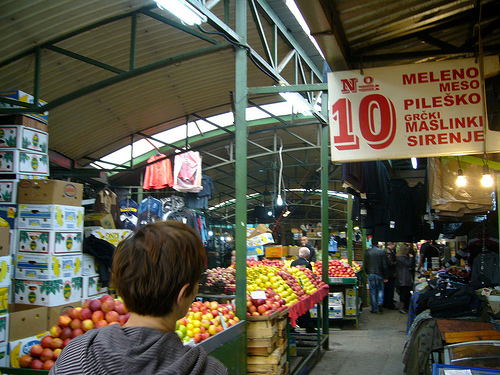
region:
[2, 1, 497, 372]
open fruit market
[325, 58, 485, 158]
red and white sale sign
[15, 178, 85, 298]
white, green, yellow and blue stacked boxes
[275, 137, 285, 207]
light bulb hanging from the ceiling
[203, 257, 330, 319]
a table full of fruit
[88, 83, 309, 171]
skylight in the ceiling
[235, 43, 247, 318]
tall green wood board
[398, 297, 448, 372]
a man shopping at the fruit market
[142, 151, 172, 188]
red jacket hanging from the ceiling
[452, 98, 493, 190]
two lamps hanging from the ceiling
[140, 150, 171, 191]
a red coat hanging from the ceiling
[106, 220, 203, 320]
the head of a person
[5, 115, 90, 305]
a stack of a boxes of a bananas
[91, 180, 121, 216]
a brown coat hanging from the ceiling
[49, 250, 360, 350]
bins of a many fruits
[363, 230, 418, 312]
people in the isle of a market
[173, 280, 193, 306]
the ear of a person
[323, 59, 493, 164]
a white sign with read letters and numbers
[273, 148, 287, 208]
a light hanging from the ceiling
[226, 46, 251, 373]
a metal pole of a building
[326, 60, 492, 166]
white sign is hanging from the ceiling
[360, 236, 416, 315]
a couple is walking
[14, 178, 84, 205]
brown cardboard box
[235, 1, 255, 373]
tall green metal pole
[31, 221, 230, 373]
person is standing next to a table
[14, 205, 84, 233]
white box on top of white box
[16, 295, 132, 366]
fruit stacked on table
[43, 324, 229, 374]
person wearin a striped hoodie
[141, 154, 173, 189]
orange shirt is hanging from the ceiling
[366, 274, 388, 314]
person wearing blue jeans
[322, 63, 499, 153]
Sign hanging from ceiling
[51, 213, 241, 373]
Woman wearing a gray sweater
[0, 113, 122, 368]
Stack of boxes behind table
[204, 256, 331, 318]
Table covered in apples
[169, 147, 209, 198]
Shirt hanging from ceiling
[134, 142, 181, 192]
Jacket hanging from ceiling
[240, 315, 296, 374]
Stack of boxes under table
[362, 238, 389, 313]
Man wearing blue jeans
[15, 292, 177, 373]
Pile of red apples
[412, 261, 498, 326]
Clothes stacked on a table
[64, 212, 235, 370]
person has short hair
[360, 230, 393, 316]
man wears black jacket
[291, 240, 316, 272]
man has gray hair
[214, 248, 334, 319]
a pile of fruits on a table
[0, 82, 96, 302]
boxes of fruits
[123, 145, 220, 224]
cloths handing from ceiling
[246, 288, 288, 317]
peaches on table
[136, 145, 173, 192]
a red jacket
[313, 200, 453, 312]
people in a market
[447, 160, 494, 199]
two bulbs are lit